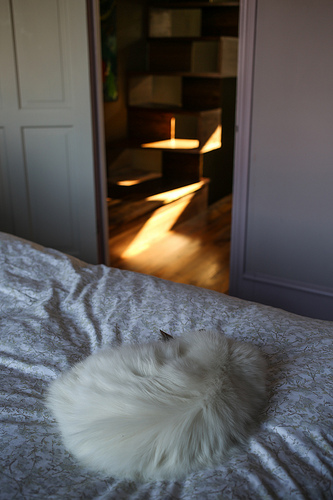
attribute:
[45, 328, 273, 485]
cat — sleeping, curled into a ball, fluffy, white, curled up, long haired, ball of fur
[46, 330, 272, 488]
fur — long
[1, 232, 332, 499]
sheet — white, patterned, floral patterned, unique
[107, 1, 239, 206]
boxes — stacked, wooden, shelves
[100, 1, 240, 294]
room — dark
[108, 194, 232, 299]
floor — wood, wooden, hardwood, red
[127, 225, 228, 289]
sunlight — yellow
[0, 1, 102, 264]
door — white, panel door, open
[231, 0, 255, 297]
door jamb — lavender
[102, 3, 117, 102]
poster — green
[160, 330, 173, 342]
ear — brown, dark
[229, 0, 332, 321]
wall — gray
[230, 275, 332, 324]
trim — lavender